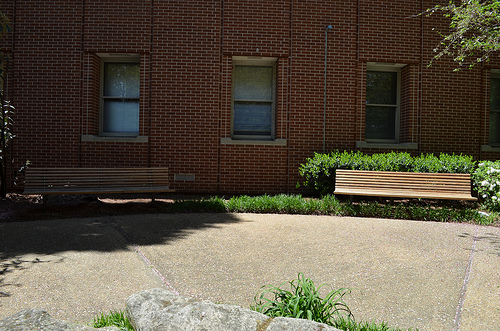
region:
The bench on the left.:
[19, 162, 176, 202]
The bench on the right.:
[325, 155, 483, 201]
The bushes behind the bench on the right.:
[308, 148, 498, 189]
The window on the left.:
[94, 51, 142, 123]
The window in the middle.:
[228, 51, 271, 136]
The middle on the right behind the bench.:
[357, 59, 409, 136]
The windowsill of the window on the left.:
[79, 130, 151, 147]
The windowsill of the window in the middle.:
[219, 130, 286, 145]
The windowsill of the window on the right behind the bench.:
[352, 136, 423, 151]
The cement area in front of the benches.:
[21, 220, 499, 329]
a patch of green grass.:
[245, 258, 415, 329]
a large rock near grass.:
[110, 275, 345, 329]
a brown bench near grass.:
[300, 143, 484, 215]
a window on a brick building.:
[210, 34, 292, 156]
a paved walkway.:
[0, 198, 497, 328]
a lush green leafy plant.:
[412, 0, 498, 142]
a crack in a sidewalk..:
[446, 207, 488, 327]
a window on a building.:
[81, 32, 171, 163]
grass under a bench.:
[168, 163, 498, 209]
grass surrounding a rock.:
[85, 226, 356, 329]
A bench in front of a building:
[15, 158, 178, 203]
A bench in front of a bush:
[302, 145, 489, 205]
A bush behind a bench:
[298, 143, 498, 210]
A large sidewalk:
[17, 203, 497, 307]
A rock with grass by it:
[67, 283, 399, 329]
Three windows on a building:
[71, 42, 428, 152]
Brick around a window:
[56, 41, 161, 155]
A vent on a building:
[168, 159, 198, 189]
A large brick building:
[16, 14, 498, 199]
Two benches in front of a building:
[10, 131, 499, 213]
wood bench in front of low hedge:
[297, 151, 480, 202]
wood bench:
[333, 167, 478, 202]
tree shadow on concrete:
[0, 195, 250, 253]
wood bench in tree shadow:
[13, 164, 175, 199]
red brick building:
[1, 1, 499, 193]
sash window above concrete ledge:
[80, 53, 148, 143]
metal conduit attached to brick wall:
[320, 23, 335, 153]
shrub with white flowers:
[472, 157, 499, 209]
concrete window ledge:
[221, 137, 291, 145]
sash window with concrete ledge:
[356, 53, 419, 148]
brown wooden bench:
[320, 157, 482, 218]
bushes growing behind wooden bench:
[317, 151, 468, 171]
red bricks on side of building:
[160, 60, 204, 132]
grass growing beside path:
[247, 280, 352, 325]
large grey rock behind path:
[124, 280, 248, 328]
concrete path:
[209, 216, 447, 278]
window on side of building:
[220, 55, 285, 146]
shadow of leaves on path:
[450, 226, 497, 268]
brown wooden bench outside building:
[18, 156, 182, 206]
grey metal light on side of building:
[318, 20, 334, 153]